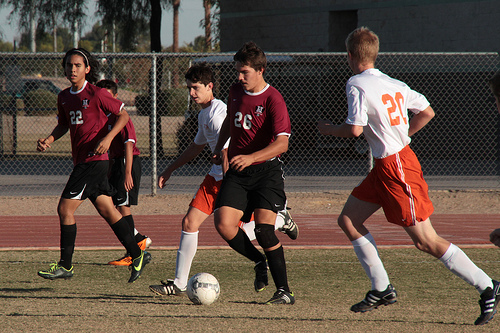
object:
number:
[233, 112, 253, 130]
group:
[33, 25, 496, 325]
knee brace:
[252, 223, 279, 249]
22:
[70, 110, 83, 126]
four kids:
[34, 25, 498, 324]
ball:
[185, 272, 222, 306]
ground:
[0, 107, 499, 333]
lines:
[363, 293, 380, 307]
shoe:
[342, 282, 399, 313]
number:
[381, 91, 409, 126]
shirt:
[343, 68, 431, 160]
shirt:
[218, 83, 291, 162]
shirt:
[191, 100, 232, 181]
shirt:
[55, 81, 125, 168]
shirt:
[109, 112, 139, 156]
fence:
[3, 50, 497, 197]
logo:
[275, 204, 281, 208]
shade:
[0, 41, 497, 179]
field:
[0, 250, 498, 333]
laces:
[46, 259, 61, 273]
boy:
[212, 43, 295, 307]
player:
[334, 25, 498, 323]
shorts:
[349, 144, 434, 227]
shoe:
[38, 262, 76, 280]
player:
[94, 79, 152, 266]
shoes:
[136, 235, 152, 249]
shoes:
[109, 256, 132, 266]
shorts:
[212, 156, 288, 212]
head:
[59, 46, 91, 83]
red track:
[0, 212, 497, 251]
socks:
[349, 233, 393, 293]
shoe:
[128, 251, 152, 283]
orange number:
[381, 92, 407, 125]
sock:
[173, 227, 200, 290]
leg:
[172, 195, 213, 287]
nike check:
[133, 252, 145, 272]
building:
[217, 0, 496, 162]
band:
[69, 46, 90, 66]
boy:
[36, 46, 153, 283]